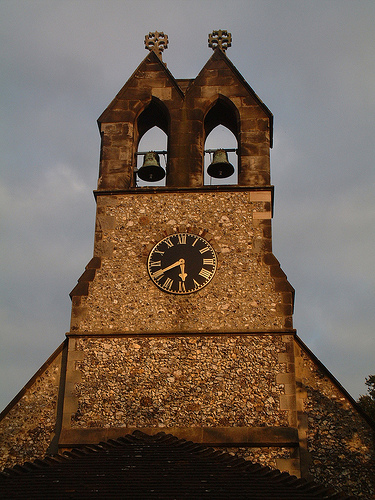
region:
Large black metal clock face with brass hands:
[143, 229, 218, 289]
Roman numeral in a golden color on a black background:
[172, 232, 188, 248]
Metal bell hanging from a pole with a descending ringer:
[205, 85, 234, 189]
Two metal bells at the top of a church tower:
[120, 102, 260, 194]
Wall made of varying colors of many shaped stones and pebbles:
[79, 335, 286, 425]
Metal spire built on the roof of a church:
[139, 28, 170, 54]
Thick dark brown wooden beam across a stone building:
[63, 414, 301, 451]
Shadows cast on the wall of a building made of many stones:
[297, 370, 357, 487]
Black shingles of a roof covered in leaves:
[30, 443, 227, 499]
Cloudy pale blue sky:
[268, 24, 374, 239]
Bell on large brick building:
[205, 149, 235, 180]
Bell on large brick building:
[137, 151, 165, 181]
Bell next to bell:
[207, 149, 233, 176]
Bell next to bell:
[137, 150, 165, 180]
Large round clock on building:
[145, 231, 217, 293]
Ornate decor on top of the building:
[206, 28, 232, 52]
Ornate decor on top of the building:
[144, 28, 169, 58]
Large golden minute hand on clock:
[147, 260, 182, 278]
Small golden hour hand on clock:
[177, 259, 187, 280]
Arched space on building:
[199, 92, 241, 185]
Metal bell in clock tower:
[137, 152, 165, 183]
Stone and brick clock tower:
[0, 29, 368, 491]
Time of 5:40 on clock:
[145, 232, 218, 294]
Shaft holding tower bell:
[138, 149, 165, 158]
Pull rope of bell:
[205, 148, 215, 186]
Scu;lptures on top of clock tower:
[144, 28, 236, 61]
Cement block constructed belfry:
[90, 46, 274, 189]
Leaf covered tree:
[356, 368, 372, 421]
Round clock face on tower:
[147, 231, 218, 296]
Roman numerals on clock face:
[148, 235, 213, 291]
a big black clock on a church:
[135, 215, 217, 307]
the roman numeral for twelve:
[169, 231, 190, 251]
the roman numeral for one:
[185, 226, 200, 248]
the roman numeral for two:
[193, 243, 211, 255]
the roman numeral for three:
[195, 253, 221, 265]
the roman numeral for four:
[196, 266, 213, 277]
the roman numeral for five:
[187, 272, 199, 292]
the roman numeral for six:
[174, 280, 186, 295]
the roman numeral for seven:
[155, 272, 170, 292]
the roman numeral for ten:
[145, 243, 162, 255]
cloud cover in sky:
[2, 2, 372, 398]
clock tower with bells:
[5, 29, 369, 497]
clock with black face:
[148, 232, 216, 296]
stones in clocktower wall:
[4, 194, 360, 477]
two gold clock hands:
[154, 258, 186, 283]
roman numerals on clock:
[148, 233, 214, 293]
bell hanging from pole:
[206, 148, 234, 179]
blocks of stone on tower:
[277, 339, 296, 429]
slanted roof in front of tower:
[7, 432, 328, 494]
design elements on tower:
[144, 29, 232, 52]